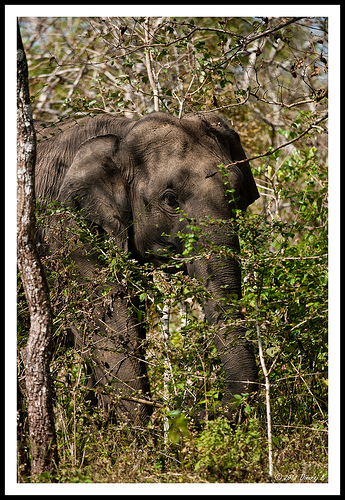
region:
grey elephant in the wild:
[52, 105, 273, 433]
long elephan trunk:
[193, 204, 265, 422]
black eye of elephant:
[150, 187, 184, 221]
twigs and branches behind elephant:
[70, 201, 272, 409]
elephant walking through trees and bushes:
[28, 92, 277, 425]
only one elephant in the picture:
[27, 102, 282, 463]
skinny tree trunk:
[22, 221, 68, 473]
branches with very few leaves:
[91, 26, 299, 118]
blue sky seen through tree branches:
[241, 27, 344, 90]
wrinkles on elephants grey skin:
[44, 129, 85, 205]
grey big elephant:
[12, 106, 260, 461]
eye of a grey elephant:
[157, 189, 186, 216]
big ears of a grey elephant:
[55, 114, 259, 258]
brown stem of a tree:
[18, 11, 52, 488]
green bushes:
[16, 16, 331, 478]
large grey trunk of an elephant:
[191, 201, 255, 440]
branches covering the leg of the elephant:
[41, 199, 159, 476]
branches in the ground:
[35, 363, 326, 485]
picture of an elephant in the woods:
[14, 15, 327, 481]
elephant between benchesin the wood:
[15, 103, 257, 452]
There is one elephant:
[62, 95, 302, 456]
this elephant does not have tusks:
[101, 220, 247, 332]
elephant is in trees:
[57, 114, 257, 330]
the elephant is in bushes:
[49, 68, 300, 388]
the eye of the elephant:
[158, 191, 215, 233]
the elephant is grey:
[51, 149, 275, 370]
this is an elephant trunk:
[133, 181, 289, 415]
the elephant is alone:
[64, 94, 296, 438]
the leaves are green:
[206, 390, 333, 461]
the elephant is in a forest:
[41, 85, 269, 337]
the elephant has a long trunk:
[155, 207, 309, 440]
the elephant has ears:
[48, 111, 271, 254]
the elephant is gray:
[17, 92, 303, 422]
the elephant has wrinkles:
[24, 98, 285, 298]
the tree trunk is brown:
[17, 104, 86, 483]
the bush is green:
[181, 153, 344, 354]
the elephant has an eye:
[143, 172, 200, 225]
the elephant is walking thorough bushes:
[30, 66, 335, 460]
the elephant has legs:
[53, 259, 196, 445]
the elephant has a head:
[56, 96, 281, 277]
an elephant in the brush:
[34, 110, 260, 418]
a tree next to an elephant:
[16, 17, 49, 478]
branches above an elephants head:
[33, 20, 325, 115]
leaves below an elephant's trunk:
[171, 388, 273, 482]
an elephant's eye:
[158, 185, 185, 215]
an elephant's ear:
[49, 134, 131, 257]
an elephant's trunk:
[193, 210, 257, 425]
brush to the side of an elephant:
[255, 139, 324, 428]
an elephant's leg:
[43, 232, 153, 424]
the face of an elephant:
[132, 124, 237, 259]